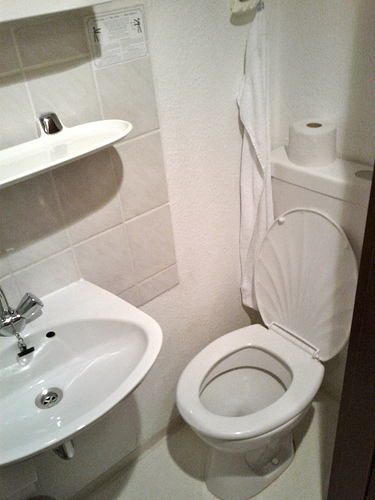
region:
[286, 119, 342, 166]
Roll of toilet paper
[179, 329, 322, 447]
Clean toilet bowl in bathroom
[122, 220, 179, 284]
Grey tile on wall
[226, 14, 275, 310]
White towel hanging down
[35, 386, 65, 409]
Clean drain in sink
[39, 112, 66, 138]
Metal fixture on wall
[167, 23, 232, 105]
White wall with paint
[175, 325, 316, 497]
a white porcelain toilet bowl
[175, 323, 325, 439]
a white plastic toilet seat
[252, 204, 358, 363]
a white plastic toilet seat lid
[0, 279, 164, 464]
a white porcelain bathroom sink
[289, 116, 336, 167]
a roll of toilet paper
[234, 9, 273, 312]
a hanging white towel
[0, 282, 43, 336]
a chrome bathroom faucet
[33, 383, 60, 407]
a chrome bathroom sink drain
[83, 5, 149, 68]
a white warning sticker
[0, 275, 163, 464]
a porcelain bathroom sink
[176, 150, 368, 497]
a small white toilet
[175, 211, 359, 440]
a toilet seat with an open lid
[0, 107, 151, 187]
a small white bathroom counter shelf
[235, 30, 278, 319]
a white towel hanging on a wall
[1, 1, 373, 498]
interior of white bathroom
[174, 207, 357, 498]
toilet with open lid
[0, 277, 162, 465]
sink attached to wall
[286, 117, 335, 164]
roll of white toilet paper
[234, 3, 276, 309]
white towel hanging from wall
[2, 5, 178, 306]
tiles on bathroom wall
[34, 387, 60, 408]
drain in bottom of sink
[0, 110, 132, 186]
shelf hanging on wall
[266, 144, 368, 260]
cover on top of tank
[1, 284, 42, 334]
knob on sink faucet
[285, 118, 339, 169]
full white roll of toilet paper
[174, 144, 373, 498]
clean white porcelain toilet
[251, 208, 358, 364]
white toilet seat lid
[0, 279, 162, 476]
white sink mounted to the wall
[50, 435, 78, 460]
silver plumbing underneath a sink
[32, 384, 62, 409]
small shiny silver drain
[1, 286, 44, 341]
silver faucet and knobs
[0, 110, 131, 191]
white shelf with silver mount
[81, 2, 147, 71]
white wall sign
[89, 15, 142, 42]
two black stick figures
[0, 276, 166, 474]
white ceramic sink on wall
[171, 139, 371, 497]
white ceramic toilet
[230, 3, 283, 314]
white towel hanging on hook